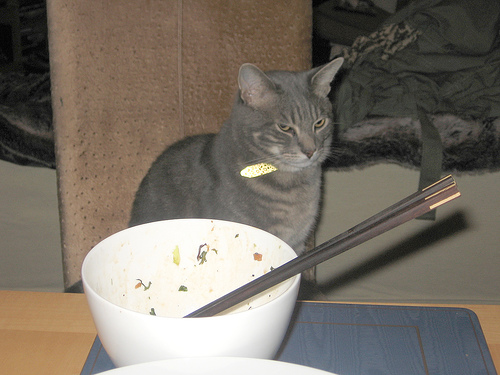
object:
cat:
[63, 56, 345, 301]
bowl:
[81, 217, 303, 367]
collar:
[237, 163, 277, 179]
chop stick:
[183, 174, 461, 318]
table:
[0, 290, 499, 374]